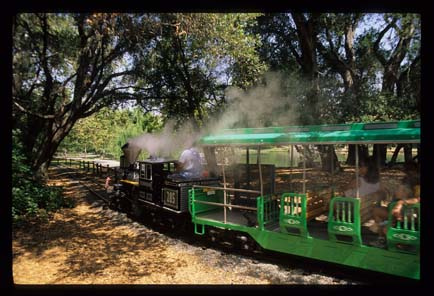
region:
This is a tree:
[59, 61, 150, 233]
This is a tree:
[35, 54, 67, 163]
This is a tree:
[22, 95, 97, 226]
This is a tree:
[277, 53, 346, 201]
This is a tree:
[332, 49, 384, 177]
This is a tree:
[371, 46, 413, 202]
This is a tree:
[392, 75, 420, 213]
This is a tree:
[186, 67, 261, 195]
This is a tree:
[231, 88, 288, 182]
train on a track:
[98, 104, 410, 268]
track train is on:
[67, 171, 103, 197]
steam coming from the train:
[136, 134, 206, 156]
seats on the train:
[311, 173, 419, 246]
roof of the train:
[198, 119, 432, 158]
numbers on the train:
[160, 186, 179, 209]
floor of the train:
[201, 209, 255, 222]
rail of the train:
[208, 182, 251, 206]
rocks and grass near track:
[211, 254, 239, 265]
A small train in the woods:
[93, 66, 432, 290]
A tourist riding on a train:
[308, 149, 384, 228]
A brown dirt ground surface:
[65, 238, 158, 277]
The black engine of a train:
[78, 131, 215, 243]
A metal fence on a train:
[191, 177, 266, 230]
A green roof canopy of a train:
[184, 113, 423, 160]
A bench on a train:
[318, 188, 385, 247]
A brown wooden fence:
[70, 153, 118, 180]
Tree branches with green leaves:
[86, 45, 238, 113]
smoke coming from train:
[122, 93, 226, 174]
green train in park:
[164, 106, 427, 286]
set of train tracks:
[62, 158, 103, 201]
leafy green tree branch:
[256, 15, 313, 88]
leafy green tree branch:
[6, 13, 61, 89]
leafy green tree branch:
[36, 7, 75, 70]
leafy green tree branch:
[97, 13, 159, 64]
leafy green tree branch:
[94, 60, 178, 89]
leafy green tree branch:
[86, 86, 195, 128]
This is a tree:
[46, 68, 108, 227]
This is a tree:
[46, 15, 139, 199]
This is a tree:
[14, 32, 63, 190]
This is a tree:
[328, 25, 367, 187]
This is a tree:
[297, 27, 337, 182]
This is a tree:
[373, 38, 399, 204]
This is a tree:
[301, 25, 340, 184]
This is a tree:
[375, 36, 395, 213]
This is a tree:
[166, 46, 278, 199]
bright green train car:
[185, 117, 419, 280]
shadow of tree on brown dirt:
[46, 207, 184, 286]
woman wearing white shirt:
[337, 159, 386, 202]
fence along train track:
[56, 157, 118, 182]